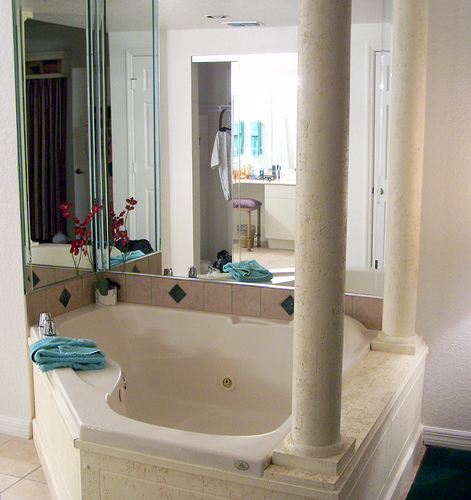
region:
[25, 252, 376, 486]
Jacuzzi tub inside restroom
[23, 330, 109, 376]
green towel on the edge of Jacuzzi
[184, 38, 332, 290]
reflections from the mirror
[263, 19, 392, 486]
a tall stone pillar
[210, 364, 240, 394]
water drain on the jicuzzi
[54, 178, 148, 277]
reflection of flower on the mirro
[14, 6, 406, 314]
a huge mirror on the wall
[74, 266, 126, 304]
a cup at the corner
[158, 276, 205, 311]
tiles on the wall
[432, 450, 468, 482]
a green type of carpet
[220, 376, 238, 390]
the jets in the bathtub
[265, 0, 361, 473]
the column on the bath tub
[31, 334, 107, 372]
the blue folded towel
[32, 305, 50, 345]
the knobs for the sink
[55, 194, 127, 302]
the plant in the corner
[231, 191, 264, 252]
the small stool near the counter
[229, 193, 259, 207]
the purple cushion on the stool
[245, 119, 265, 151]
the hand towel on the wall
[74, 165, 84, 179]
the door handle in the mirror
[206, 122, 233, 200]
the shirt hanging in the closet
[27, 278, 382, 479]
large whirlpool tub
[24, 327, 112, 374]
folded blue towel next to the tub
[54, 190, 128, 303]
dark pink orchid plant by the tub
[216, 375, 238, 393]
jet spout in the tub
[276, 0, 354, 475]
marble pillar on the tub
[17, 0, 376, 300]
mirrors reflecting the back view of the bathroom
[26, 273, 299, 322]
decorative tiling above the tub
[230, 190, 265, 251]
stool seen in the mirror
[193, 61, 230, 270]
closet seen in the mirror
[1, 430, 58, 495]
tile on the ground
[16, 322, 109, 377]
a green towel folded on the side of a tub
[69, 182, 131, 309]
a pot with red flowers in it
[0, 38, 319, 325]
a large mirror above a tub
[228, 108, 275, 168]
a towel hanging on a towel rod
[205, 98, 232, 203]
a white shirt hanging in a closet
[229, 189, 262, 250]
a wood stool with a cushion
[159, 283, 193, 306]
a green tile in the shape of a triangle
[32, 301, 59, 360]
silver water knobs on a table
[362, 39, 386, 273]
a white door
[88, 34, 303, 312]
reflection in a mirror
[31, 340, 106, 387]
blue towel on tub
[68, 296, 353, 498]
white tub in bathroom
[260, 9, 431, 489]
white columns near tub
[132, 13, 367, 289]
mirror is behind tub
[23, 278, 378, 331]
brown and green tile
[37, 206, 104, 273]
red flower in pot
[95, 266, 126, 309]
white pot on corner of wall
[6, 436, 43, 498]
light brown floor tile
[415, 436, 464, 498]
black rug outside tub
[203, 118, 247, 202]
white shirt on hanger in closet